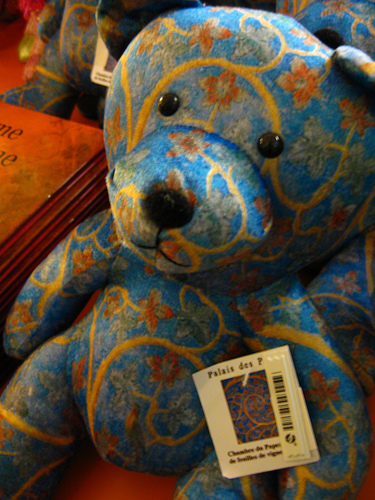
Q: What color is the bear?
A: Blue.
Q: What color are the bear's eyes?
A: Black.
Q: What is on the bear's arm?
A: A tag.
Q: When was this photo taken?
A: In the daytime.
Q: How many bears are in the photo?
A: One.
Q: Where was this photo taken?
A: In a store.